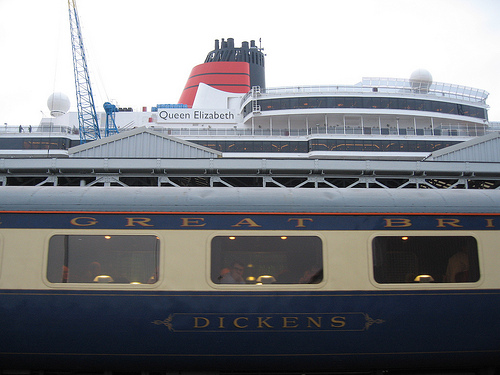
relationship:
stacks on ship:
[206, 34, 264, 66] [5, 37, 484, 369]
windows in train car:
[367, 230, 482, 285] [4, 184, 496, 360]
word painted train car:
[68, 214, 314, 234] [4, 184, 496, 360]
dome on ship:
[41, 87, 70, 114] [5, 37, 484, 369]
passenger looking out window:
[219, 260, 249, 283] [208, 233, 325, 285]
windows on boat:
[255, 103, 437, 138] [4, 28, 498, 372]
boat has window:
[4, 28, 498, 372] [45, 231, 160, 283]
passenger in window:
[219, 260, 246, 284] [209, 234, 324, 285]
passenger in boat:
[219, 260, 246, 284] [0, 0, 498, 361]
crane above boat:
[63, 0, 100, 144] [4, 28, 498, 372]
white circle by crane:
[46, 94, 72, 117] [56, 0, 105, 146]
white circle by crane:
[408, 69, 435, 92] [56, 0, 105, 146]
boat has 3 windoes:
[4, 28, 498, 372] [57, 229, 155, 287]